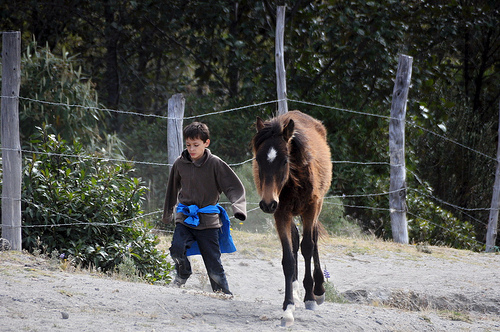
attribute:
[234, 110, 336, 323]
horse — running, walking, behind, brown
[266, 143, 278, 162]
spot — white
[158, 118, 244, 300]
boy — running, walking, young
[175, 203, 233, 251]
coat — tied, jacket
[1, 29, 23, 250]
stick — wood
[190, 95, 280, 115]
fence — wire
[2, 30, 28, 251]
post — wooden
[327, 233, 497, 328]
field — grass, dirt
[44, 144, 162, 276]
bush — green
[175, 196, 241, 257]
jacket — blue, tied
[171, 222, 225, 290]
jeans — blue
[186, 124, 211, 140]
hair — black, dark, brown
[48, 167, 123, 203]
leaves — green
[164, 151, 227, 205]
shirt — green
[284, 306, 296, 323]
foot — white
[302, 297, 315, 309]
foot — white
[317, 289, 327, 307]
foot — white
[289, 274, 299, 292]
foot — white